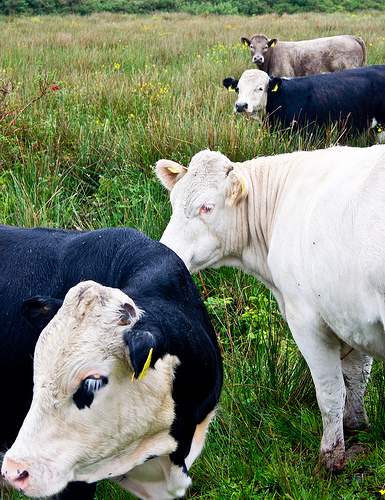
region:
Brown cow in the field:
[233, 12, 367, 69]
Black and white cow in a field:
[218, 55, 381, 125]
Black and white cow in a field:
[0, 209, 218, 492]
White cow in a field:
[137, 134, 383, 411]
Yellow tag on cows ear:
[113, 338, 153, 396]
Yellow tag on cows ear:
[161, 153, 181, 179]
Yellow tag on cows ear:
[228, 170, 253, 216]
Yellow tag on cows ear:
[266, 76, 285, 104]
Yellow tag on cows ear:
[216, 74, 243, 98]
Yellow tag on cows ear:
[236, 33, 278, 49]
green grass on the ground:
[247, 433, 309, 493]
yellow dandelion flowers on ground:
[147, 70, 170, 103]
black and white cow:
[0, 224, 214, 499]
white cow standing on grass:
[167, 151, 383, 462]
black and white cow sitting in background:
[232, 70, 382, 139]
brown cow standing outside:
[245, 36, 375, 72]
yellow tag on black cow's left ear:
[133, 347, 161, 385]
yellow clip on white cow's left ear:
[234, 173, 259, 205]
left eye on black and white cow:
[76, 370, 119, 427]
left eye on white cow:
[201, 202, 223, 230]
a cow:
[0, 255, 234, 499]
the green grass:
[239, 424, 309, 486]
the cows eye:
[72, 365, 119, 398]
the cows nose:
[0, 459, 29, 489]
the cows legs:
[301, 351, 373, 456]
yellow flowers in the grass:
[136, 74, 170, 104]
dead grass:
[151, 14, 203, 46]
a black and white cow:
[221, 69, 382, 116]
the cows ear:
[121, 331, 165, 378]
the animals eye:
[197, 201, 225, 215]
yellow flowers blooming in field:
[109, 26, 244, 104]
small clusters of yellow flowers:
[96, 23, 251, 109]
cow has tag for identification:
[119, 329, 156, 388]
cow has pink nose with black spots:
[3, 456, 32, 494]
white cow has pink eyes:
[199, 200, 216, 218]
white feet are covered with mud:
[308, 345, 375, 479]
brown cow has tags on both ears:
[240, 34, 367, 75]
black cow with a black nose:
[222, 65, 283, 116]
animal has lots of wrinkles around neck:
[214, 157, 295, 275]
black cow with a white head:
[3, 222, 222, 496]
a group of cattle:
[17, 14, 371, 478]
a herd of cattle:
[11, 34, 382, 496]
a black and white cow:
[11, 226, 231, 491]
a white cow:
[152, 146, 383, 479]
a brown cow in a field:
[239, 33, 366, 70]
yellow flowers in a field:
[107, 51, 176, 124]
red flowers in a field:
[35, 80, 74, 103]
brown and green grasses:
[7, 12, 218, 91]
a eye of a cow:
[68, 367, 108, 396]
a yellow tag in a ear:
[129, 352, 153, 386]